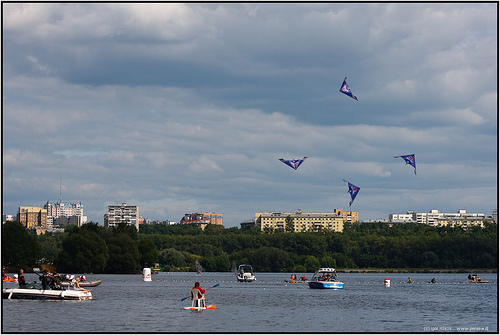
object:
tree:
[31, 233, 63, 271]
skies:
[0, 0, 500, 223]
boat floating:
[13, 274, 19, 284]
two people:
[16, 264, 65, 290]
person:
[407, 276, 413, 282]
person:
[431, 277, 437, 283]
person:
[290, 274, 294, 279]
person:
[73, 277, 91, 292]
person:
[468, 274, 472, 280]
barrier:
[384, 277, 391, 287]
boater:
[324, 276, 333, 282]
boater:
[17, 269, 26, 289]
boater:
[80, 275, 86, 282]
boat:
[308, 267, 344, 289]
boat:
[183, 304, 217, 310]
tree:
[62, 227, 110, 273]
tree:
[256, 245, 290, 272]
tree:
[320, 256, 337, 268]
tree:
[0, 220, 40, 271]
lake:
[0, 272, 499, 334]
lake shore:
[2, 267, 500, 274]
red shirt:
[190, 287, 206, 299]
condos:
[256, 214, 344, 234]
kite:
[277, 156, 308, 170]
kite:
[342, 178, 361, 207]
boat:
[236, 264, 256, 282]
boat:
[31, 278, 102, 287]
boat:
[145, 267, 161, 274]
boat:
[459, 280, 488, 283]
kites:
[392, 154, 417, 176]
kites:
[338, 76, 359, 101]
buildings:
[16, 206, 47, 236]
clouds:
[0, 0, 500, 229]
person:
[190, 281, 207, 307]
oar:
[178, 283, 220, 303]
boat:
[0, 287, 93, 301]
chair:
[189, 289, 205, 308]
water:
[0, 270, 500, 330]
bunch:
[276, 71, 416, 207]